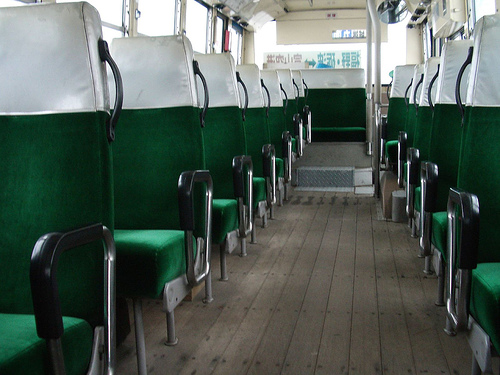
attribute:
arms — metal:
[173, 171, 213, 268]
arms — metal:
[433, 187, 480, 332]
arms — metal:
[405, 157, 436, 249]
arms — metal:
[229, 145, 256, 238]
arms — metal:
[41, 229, 123, 371]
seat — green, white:
[409, 57, 441, 237]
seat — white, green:
[274, 65, 311, 157]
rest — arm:
[162, 150, 253, 293]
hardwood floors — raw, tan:
[284, 214, 419, 367]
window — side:
[136, 0, 184, 30]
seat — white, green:
[241, 62, 273, 229]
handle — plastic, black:
[100, 38, 125, 138]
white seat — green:
[98, 24, 229, 251]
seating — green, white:
[3, 2, 119, 374]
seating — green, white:
[110, 31, 206, 323]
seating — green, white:
[194, 47, 256, 275]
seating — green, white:
[240, 61, 283, 234]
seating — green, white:
[448, 14, 498, 371]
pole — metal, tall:
[358, 11, 402, 174]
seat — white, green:
[4, 3, 147, 373]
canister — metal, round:
[390, 185, 410, 225]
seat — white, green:
[387, 16, 495, 307]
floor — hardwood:
[98, 182, 477, 372]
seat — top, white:
[68, 5, 238, 356]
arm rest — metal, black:
[28, 220, 103, 339]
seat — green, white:
[260, 69, 292, 172]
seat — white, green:
[95, 220, 194, 297]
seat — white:
[0, 304, 100, 369]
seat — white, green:
[204, 192, 240, 241]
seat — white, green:
[262, 157, 284, 182]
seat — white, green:
[464, 259, 499, 324]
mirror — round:
[377, 0, 401, 25]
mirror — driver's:
[377, 2, 420, 28]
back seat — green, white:
[296, 64, 378, 147]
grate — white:
[301, 160, 361, 190]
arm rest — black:
[26, 220, 115, 373]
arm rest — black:
[176, 167, 213, 282]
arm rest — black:
[232, 153, 256, 238]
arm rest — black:
[261, 140, 276, 206]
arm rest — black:
[445, 185, 481, 334]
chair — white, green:
[444, 13, 499, 373]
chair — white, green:
[0, 0, 124, 373]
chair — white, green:
[108, 35, 210, 373]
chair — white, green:
[195, 51, 253, 280]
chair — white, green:
[235, 60, 275, 230]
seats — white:
[374, 10, 498, 374]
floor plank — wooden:
[180, 178, 462, 373]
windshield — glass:
[236, 11, 418, 92]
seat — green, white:
[460, 8, 484, 357]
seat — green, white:
[420, 32, 477, 294]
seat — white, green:
[410, 58, 433, 239]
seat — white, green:
[382, 59, 422, 220]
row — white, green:
[367, 24, 484, 364]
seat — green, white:
[193, 50, 251, 280]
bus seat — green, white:
[2, 7, 125, 367]